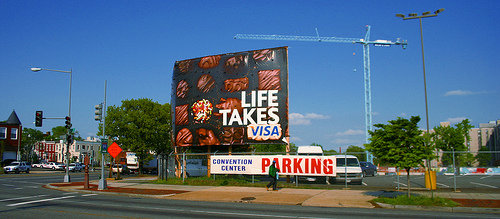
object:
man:
[264, 160, 282, 191]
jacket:
[267, 164, 283, 180]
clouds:
[287, 112, 330, 127]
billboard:
[170, 46, 291, 148]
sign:
[104, 140, 122, 160]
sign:
[208, 156, 336, 178]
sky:
[0, 0, 499, 154]